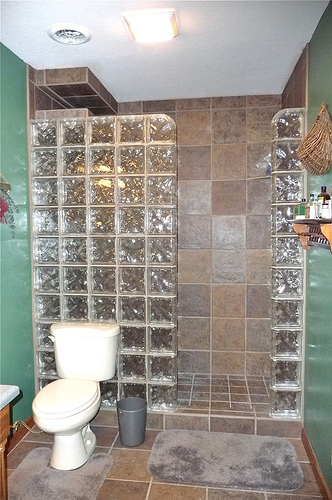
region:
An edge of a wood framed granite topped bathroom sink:
[0, 382, 21, 498]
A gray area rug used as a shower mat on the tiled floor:
[147, 429, 304, 493]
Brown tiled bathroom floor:
[8, 408, 327, 498]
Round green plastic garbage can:
[115, 395, 149, 446]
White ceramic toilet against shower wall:
[30, 319, 120, 472]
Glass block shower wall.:
[25, 109, 305, 397]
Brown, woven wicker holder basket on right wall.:
[294, 102, 331, 174]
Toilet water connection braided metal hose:
[13, 417, 46, 435]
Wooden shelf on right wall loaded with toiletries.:
[289, 184, 331, 251]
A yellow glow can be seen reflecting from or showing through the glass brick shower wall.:
[59, 147, 147, 203]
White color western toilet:
[12, 309, 117, 471]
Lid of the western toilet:
[32, 391, 81, 409]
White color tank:
[61, 316, 134, 366]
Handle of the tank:
[44, 330, 57, 342]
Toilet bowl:
[39, 426, 79, 435]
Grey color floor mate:
[163, 429, 297, 496]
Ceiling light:
[116, 7, 186, 53]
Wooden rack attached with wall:
[287, 185, 329, 248]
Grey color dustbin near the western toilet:
[111, 392, 147, 446]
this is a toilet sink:
[40, 373, 86, 462]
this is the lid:
[35, 378, 88, 410]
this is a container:
[113, 398, 152, 442]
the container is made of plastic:
[124, 422, 139, 439]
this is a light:
[130, 10, 172, 39]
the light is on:
[128, 13, 176, 47]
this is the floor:
[104, 447, 161, 497]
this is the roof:
[206, 9, 281, 85]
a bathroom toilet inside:
[35, 301, 161, 481]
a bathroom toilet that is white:
[20, 326, 114, 491]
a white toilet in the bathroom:
[3, 319, 184, 497]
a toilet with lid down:
[17, 303, 122, 454]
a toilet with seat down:
[7, 292, 136, 434]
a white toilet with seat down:
[22, 310, 142, 492]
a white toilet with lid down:
[31, 307, 142, 479]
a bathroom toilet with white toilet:
[18, 330, 134, 474]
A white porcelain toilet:
[25, 313, 127, 475]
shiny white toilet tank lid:
[47, 322, 118, 337]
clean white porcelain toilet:
[33, 319, 120, 470]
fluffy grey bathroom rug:
[147, 427, 303, 492]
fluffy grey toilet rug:
[5, 445, 114, 499]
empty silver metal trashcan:
[114, 395, 147, 446]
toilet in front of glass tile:
[30, 319, 121, 472]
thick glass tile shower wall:
[30, 108, 304, 418]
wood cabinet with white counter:
[0, 383, 19, 499]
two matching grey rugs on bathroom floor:
[8, 427, 304, 498]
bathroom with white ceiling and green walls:
[0, 0, 330, 498]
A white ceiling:
[2, 0, 329, 102]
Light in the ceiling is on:
[0, 0, 328, 100]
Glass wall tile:
[28, 112, 177, 409]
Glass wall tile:
[268, 104, 302, 415]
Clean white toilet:
[28, 318, 118, 468]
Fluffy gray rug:
[143, 427, 302, 490]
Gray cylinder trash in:
[114, 394, 146, 445]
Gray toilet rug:
[5, 444, 113, 495]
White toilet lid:
[30, 376, 96, 414]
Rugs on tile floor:
[5, 423, 323, 498]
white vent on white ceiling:
[0, 0, 329, 104]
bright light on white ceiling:
[0, 0, 331, 103]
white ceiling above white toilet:
[0, 1, 331, 469]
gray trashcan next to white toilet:
[29, 319, 148, 468]